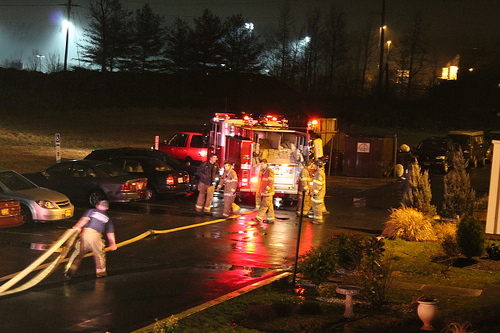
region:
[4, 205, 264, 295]
the hose is long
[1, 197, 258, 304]
the hose is yellow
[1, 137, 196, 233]
the cars are parked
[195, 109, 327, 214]
the fire truck with the hose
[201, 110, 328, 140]
the lights on the fire truck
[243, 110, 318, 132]
the lights are red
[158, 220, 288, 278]
the ground is wet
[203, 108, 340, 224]
the fire truck is red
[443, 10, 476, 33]
the sky is black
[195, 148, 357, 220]
the firefighters around the fire truck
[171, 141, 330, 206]
people outside a truck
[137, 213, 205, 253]
hose on the ground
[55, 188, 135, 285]
man holding a hose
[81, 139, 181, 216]
cars parked next to people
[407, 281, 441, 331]
pot next to the street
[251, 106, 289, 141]
lights on the truck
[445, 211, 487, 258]
bush next to the street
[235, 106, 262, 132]
red light on the truck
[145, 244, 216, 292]
wet street below the people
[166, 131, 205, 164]
red car in the parking lot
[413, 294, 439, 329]
circular concrete plant holder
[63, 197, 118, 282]
fire fighter pulling fire hose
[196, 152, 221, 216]
fire fighter with hands in his pockets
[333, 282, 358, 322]
concrete bird bath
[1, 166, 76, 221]
front of silver car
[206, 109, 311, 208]
fire truck with lights on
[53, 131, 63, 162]
blue and white parking sign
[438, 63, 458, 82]
two bright lights on the hill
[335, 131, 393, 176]
large brown dumpster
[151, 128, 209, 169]
small red car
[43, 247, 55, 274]
the hose is yellow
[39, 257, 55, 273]
the hose is yellow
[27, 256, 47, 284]
the hose is yellow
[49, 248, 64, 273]
the hose is yellow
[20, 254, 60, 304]
the hose is yellow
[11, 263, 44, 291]
the hose is yellow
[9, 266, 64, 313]
the hose is yellow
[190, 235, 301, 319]
the road is wet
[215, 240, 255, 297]
the road is wet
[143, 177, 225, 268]
the road is wet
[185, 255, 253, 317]
the road is wet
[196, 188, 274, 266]
the road is wet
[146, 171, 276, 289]
the road is wet